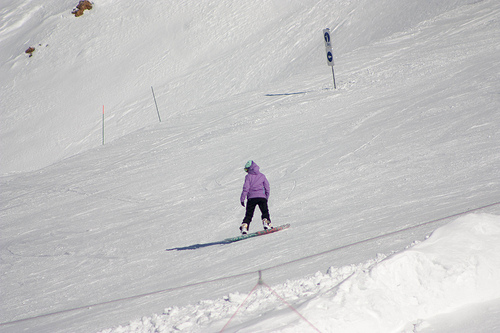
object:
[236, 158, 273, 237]
person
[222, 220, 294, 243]
snowboard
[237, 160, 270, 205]
jacket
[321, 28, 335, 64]
sign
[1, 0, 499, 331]
snow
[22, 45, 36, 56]
rocks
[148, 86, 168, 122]
poles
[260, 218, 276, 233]
boots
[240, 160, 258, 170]
hat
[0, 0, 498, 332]
ground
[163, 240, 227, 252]
shadow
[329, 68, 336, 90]
pole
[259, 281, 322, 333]
string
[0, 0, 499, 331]
hill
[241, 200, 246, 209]
glove